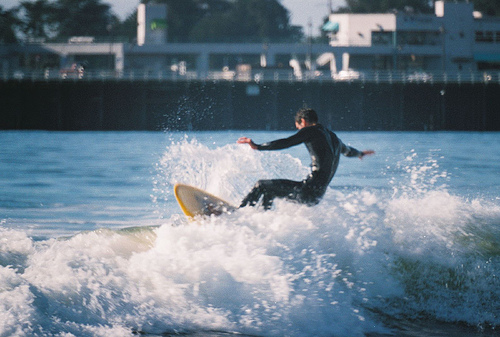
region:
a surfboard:
[173, 173, 211, 216]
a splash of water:
[190, 149, 248, 181]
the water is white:
[223, 230, 343, 288]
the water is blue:
[14, 138, 102, 186]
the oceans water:
[36, 143, 119, 210]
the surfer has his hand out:
[231, 129, 299, 152]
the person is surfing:
[222, 107, 383, 226]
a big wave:
[151, 213, 400, 323]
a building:
[324, 10, 440, 42]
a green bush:
[201, 10, 281, 34]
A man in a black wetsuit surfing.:
[236, 107, 375, 209]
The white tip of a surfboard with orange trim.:
[173, 181, 238, 219]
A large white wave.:
[1, 184, 497, 335]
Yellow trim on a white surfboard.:
[174, 181, 225, 221]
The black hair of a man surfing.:
[292, 103, 322, 126]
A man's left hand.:
[235, 135, 255, 148]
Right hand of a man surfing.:
[357, 145, 375, 162]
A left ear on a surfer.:
[296, 114, 306, 128]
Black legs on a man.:
[238, 175, 316, 222]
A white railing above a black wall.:
[0, 68, 499, 83]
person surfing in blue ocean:
[148, 98, 342, 228]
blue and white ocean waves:
[15, 151, 70, 207]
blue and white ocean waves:
[114, 273, 149, 309]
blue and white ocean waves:
[206, 251, 278, 304]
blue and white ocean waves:
[295, 239, 348, 309]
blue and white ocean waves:
[348, 215, 396, 301]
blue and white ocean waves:
[416, 198, 445, 230]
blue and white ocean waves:
[88, 181, 133, 220]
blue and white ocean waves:
[46, 140, 87, 192]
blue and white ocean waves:
[95, 149, 131, 195]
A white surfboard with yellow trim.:
[166, 176, 227, 220]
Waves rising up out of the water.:
[139, 217, 361, 321]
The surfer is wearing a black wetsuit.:
[226, 105, 383, 219]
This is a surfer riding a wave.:
[146, 89, 373, 245]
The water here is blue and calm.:
[19, 130, 126, 199]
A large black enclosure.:
[13, 70, 494, 130]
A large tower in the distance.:
[135, 1, 173, 43]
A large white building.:
[323, 0, 498, 87]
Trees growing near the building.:
[179, 3, 299, 44]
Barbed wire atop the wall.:
[33, 69, 497, 82]